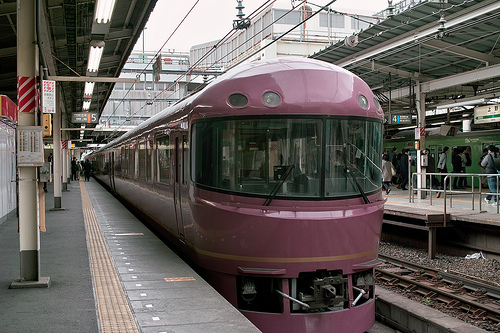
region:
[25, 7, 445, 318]
a commuter train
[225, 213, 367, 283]
the train is purple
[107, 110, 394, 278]
the train is very long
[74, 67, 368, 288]
the train is at the depot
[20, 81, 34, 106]
A red and white striped sign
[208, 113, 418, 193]
large rounded windows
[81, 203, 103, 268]
yellow lines next to the sidewalk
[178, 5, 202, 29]
a gray day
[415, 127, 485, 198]
people on the platform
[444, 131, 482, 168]
the train is green.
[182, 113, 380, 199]
The windsjile of the train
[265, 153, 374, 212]
The windhield wipers on the front glass window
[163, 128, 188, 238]
The closed door on the train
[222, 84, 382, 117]
The lights over the front windshield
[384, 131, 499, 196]
People getting on the green train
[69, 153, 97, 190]
People waiting on the train platform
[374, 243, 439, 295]
The tracks next to the purple train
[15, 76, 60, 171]
Postings on the platform pillars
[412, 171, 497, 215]
Saftey rails on the train platform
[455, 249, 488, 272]
A piece of trash on the rocks near the platform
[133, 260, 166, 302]
part of a floor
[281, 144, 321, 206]
part of a window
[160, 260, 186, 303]
part of a floor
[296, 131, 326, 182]
part of a window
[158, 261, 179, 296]
part of a win dow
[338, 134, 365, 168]
part of a window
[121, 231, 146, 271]
part of a floor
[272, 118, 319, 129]
part of a window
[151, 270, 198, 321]
part of a floor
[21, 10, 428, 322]
the train is in the depot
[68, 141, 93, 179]
people are standing next to the train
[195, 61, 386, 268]
the train is light purple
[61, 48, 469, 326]
picture taken during the day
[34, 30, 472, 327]
picture taken outdoors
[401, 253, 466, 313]
the tracks are empty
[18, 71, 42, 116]
a red and white sign on a post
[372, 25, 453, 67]
the platform is covered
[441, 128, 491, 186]
a green train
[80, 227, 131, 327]
A yellow safety line painted concrete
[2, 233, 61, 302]
The base of a metal pillar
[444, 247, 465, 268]
Gravel on a train track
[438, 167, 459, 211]
A metal hand railing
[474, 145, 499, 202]
a person at a train station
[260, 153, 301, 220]
A windshield wiper on a train window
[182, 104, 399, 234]
The front windshield of a train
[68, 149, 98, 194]
People standing at a train platform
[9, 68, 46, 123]
A red and white safety sign on a pole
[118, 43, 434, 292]
A train stopped at a station